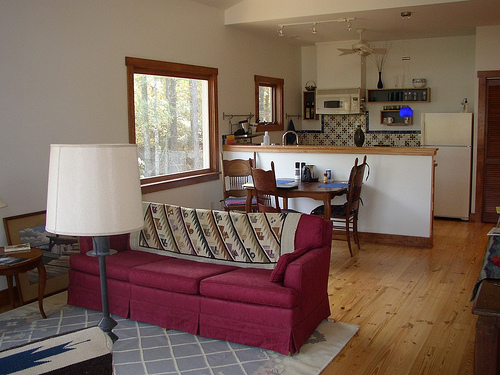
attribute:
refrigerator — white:
[420, 112, 471, 220]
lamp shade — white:
[40, 136, 148, 243]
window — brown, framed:
[122, 52, 224, 197]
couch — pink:
[68, 196, 333, 354]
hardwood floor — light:
[319, 214, 494, 374]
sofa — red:
[1, 135, 399, 363]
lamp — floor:
[32, 132, 154, 344]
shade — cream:
[41, 135, 150, 242]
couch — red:
[144, 219, 320, 340]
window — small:
[253, 70, 290, 129]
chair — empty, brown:
[206, 152, 266, 211]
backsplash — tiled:
[288, 107, 422, 144]